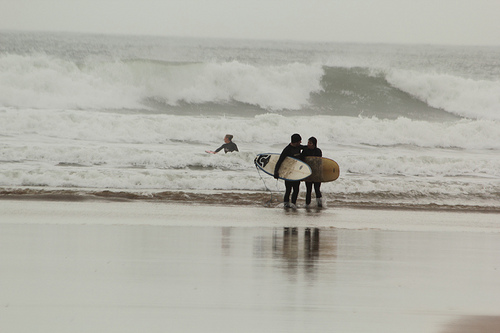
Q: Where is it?
A: This is at the ocean.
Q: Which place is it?
A: It is an ocean.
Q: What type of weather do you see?
A: It is cloudy.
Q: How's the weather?
A: It is cloudy.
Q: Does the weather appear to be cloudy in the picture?
A: Yes, it is cloudy.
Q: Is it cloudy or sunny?
A: It is cloudy.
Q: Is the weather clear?
A: No, it is cloudy.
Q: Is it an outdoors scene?
A: Yes, it is outdoors.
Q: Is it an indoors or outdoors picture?
A: It is outdoors.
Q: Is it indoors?
A: No, it is outdoors.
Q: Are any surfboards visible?
A: Yes, there is a surfboard.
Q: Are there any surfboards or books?
A: Yes, there is a surfboard.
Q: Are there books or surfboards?
A: Yes, there is a surfboard.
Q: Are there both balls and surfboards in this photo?
A: No, there is a surfboard but no balls.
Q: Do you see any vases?
A: No, there are no vases.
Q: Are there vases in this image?
A: No, there are no vases.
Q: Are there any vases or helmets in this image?
A: No, there are no vases or helmets.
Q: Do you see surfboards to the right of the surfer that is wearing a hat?
A: Yes, there is a surfboard to the right of the surfer.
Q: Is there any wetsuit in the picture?
A: Yes, there is a wetsuit.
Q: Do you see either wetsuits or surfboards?
A: Yes, there is a wetsuit.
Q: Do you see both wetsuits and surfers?
A: Yes, there are both a wetsuit and a surfer.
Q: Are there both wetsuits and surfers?
A: Yes, there are both a wetsuit and a surfer.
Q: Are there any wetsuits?
A: Yes, there is a wetsuit.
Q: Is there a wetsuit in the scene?
A: Yes, there is a wetsuit.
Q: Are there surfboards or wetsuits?
A: Yes, there is a wetsuit.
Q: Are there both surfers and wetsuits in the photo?
A: Yes, there are both a wetsuit and a surfer.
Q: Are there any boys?
A: No, there are no boys.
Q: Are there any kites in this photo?
A: No, there are no kites.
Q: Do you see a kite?
A: No, there are no kites.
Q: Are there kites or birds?
A: No, there are no kites or birds.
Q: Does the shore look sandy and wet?
A: Yes, the shore is sandy and wet.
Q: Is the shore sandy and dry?
A: No, the shore is sandy but wet.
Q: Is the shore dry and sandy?
A: No, the shore is sandy but wet.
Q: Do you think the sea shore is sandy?
A: Yes, the sea shore is sandy.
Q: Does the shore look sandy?
A: Yes, the shore is sandy.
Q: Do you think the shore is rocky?
A: No, the shore is sandy.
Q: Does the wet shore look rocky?
A: No, the sea shore is sandy.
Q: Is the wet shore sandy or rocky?
A: The shore is sandy.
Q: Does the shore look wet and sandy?
A: Yes, the shore is wet and sandy.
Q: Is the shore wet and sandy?
A: Yes, the shore is wet and sandy.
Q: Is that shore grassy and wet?
A: No, the shore is wet but sandy.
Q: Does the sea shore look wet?
A: Yes, the sea shore is wet.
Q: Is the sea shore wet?
A: Yes, the sea shore is wet.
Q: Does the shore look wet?
A: Yes, the shore is wet.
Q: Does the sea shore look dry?
A: No, the sea shore is wet.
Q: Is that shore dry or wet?
A: The shore is wet.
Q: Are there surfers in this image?
A: Yes, there is a surfer.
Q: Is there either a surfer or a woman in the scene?
A: Yes, there is a surfer.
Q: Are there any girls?
A: No, there are no girls.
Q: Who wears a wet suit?
A: The surfer wears a wet suit.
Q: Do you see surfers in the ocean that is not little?
A: Yes, there is a surfer in the ocean.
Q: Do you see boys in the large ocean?
A: No, there is a surfer in the ocean.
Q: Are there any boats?
A: No, there are no boats.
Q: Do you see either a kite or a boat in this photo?
A: No, there are no boats or kites.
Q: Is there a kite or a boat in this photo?
A: No, there are no boats or kites.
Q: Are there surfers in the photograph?
A: Yes, there is a surfer.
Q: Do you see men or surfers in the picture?
A: Yes, there is a surfer.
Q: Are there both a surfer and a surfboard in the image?
A: Yes, there are both a surfer and a surfboard.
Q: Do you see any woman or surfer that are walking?
A: Yes, the surfer is walking.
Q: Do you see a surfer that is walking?
A: Yes, there is a surfer that is walking.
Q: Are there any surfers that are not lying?
A: Yes, there is a surfer that is walking.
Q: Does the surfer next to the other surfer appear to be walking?
A: Yes, the surfer is walking.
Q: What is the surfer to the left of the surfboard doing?
A: The surfer is walking.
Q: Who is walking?
A: The surfer is walking.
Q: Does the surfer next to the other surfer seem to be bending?
A: No, the surfer is walking.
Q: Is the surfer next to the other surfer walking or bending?
A: The surfer is walking.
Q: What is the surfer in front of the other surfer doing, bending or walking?
A: The surfer is walking.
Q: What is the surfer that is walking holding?
A: The surfer is holding the surfboard.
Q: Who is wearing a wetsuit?
A: The surfer is wearing a wetsuit.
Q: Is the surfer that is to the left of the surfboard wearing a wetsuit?
A: Yes, the surfer is wearing a wetsuit.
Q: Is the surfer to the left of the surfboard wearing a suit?
A: No, the surfer is wearing a wetsuit.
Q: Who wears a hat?
A: The surfer wears a hat.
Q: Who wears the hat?
A: The surfer wears a hat.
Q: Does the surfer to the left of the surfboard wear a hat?
A: Yes, the surfer wears a hat.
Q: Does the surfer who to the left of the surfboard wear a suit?
A: No, the surfer wears a hat.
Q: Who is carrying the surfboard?
A: The surfer is carrying the surfboard.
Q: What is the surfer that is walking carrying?
A: The surfer is carrying a surfboard.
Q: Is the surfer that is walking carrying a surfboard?
A: Yes, the surfer is carrying a surfboard.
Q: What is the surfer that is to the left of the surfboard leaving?
A: The surfer is leaving the ocean.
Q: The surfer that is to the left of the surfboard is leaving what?
A: The surfer is leaving the ocean.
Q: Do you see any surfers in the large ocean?
A: Yes, there is a surfer in the ocean.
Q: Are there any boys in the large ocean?
A: No, there is a surfer in the ocean.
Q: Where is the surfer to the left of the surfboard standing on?
A: The surfer is standing on the shore.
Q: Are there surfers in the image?
A: Yes, there is a surfer.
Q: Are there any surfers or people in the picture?
A: Yes, there is a surfer.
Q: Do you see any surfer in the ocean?
A: Yes, there is a surfer in the ocean.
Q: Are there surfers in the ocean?
A: Yes, there is a surfer in the ocean.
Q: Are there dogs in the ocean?
A: No, there is a surfer in the ocean.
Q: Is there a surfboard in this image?
A: Yes, there is a surfboard.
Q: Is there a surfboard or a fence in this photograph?
A: Yes, there is a surfboard.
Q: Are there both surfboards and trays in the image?
A: No, there is a surfboard but no trays.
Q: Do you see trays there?
A: No, there are no trays.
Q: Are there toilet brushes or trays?
A: No, there are no trays or toilet brushes.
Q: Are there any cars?
A: No, there are no cars.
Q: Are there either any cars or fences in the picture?
A: No, there are no cars or fences.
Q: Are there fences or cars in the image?
A: No, there are no cars or fences.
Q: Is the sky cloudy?
A: Yes, the sky is cloudy.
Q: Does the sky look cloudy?
A: Yes, the sky is cloudy.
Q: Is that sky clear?
A: No, the sky is cloudy.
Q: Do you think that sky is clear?
A: No, the sky is cloudy.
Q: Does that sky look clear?
A: No, the sky is cloudy.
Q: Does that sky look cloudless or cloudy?
A: The sky is cloudy.